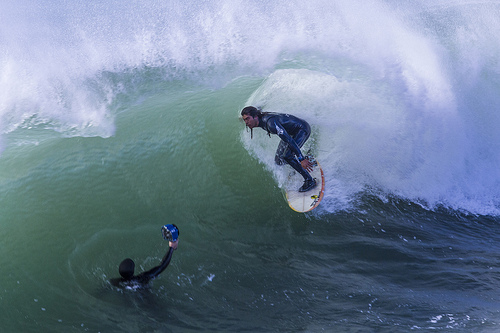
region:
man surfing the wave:
[216, 68, 353, 228]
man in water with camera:
[78, 213, 222, 326]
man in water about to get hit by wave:
[19, 65, 220, 324]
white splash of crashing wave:
[228, 49, 484, 226]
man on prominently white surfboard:
[229, 97, 335, 224]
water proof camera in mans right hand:
[155, 217, 195, 252]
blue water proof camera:
[155, 212, 194, 251]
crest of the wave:
[13, 51, 239, 154]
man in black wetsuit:
[67, 221, 204, 321]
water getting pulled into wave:
[220, 225, 487, 324]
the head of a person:
[236, 99, 266, 134]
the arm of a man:
[269, 116, 323, 175]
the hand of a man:
[296, 151, 321, 173]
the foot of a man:
[296, 171, 319, 196]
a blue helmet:
[156, 214, 183, 245]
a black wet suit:
[256, 103, 314, 184]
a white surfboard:
[276, 151, 333, 219]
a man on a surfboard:
[234, 99, 339, 219]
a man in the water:
[102, 216, 198, 297]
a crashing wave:
[0, 0, 498, 231]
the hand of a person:
[156, 227, 175, 278]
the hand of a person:
[271, 122, 308, 165]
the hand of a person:
[91, 280, 108, 301]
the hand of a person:
[258, 128, 267, 133]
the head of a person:
[116, 250, 140, 277]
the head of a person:
[229, 98, 271, 133]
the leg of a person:
[286, 131, 323, 198]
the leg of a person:
[265, 135, 294, 162]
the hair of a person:
[243, 104, 263, 117]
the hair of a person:
[116, 255, 133, 282]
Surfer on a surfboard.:
[238, 106, 317, 193]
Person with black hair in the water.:
[98, 238, 178, 296]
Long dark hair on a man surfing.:
[238, 106, 262, 139]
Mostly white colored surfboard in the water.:
[281, 157, 324, 213]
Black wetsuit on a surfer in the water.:
[261, 108, 317, 193]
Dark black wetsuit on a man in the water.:
[104, 246, 176, 296]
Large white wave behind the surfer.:
[247, 73, 432, 211]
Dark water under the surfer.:
[292, 212, 499, 331]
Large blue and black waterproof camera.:
[158, 223, 182, 242]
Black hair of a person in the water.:
[118, 256, 137, 279]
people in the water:
[51, 75, 313, 314]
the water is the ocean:
[94, 68, 339, 265]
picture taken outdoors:
[54, 42, 422, 267]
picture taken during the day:
[62, 53, 453, 330]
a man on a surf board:
[197, 117, 411, 246]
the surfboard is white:
[237, 149, 347, 220]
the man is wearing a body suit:
[214, 99, 349, 201]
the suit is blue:
[242, 102, 314, 175]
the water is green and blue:
[98, 125, 311, 287]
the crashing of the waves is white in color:
[329, 49, 470, 191]